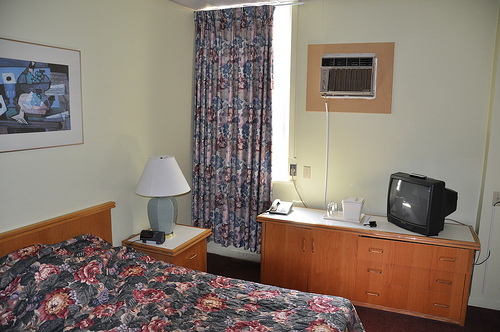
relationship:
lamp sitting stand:
[135, 155, 190, 238] [127, 223, 213, 271]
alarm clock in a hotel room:
[139, 224, 166, 244] [1, 2, 495, 330]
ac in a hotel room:
[319, 53, 378, 102] [5, 5, 491, 324]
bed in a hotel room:
[1, 201, 368, 329] [5, 5, 491, 324]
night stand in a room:
[120, 215, 221, 283] [5, 5, 491, 324]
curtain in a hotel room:
[190, 24, 295, 256] [25, 17, 477, 325]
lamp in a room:
[135, 155, 190, 237] [5, 5, 491, 324]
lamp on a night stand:
[135, 155, 190, 238] [124, 195, 204, 247]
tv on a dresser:
[382, 170, 461, 239] [254, 192, 476, 322]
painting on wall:
[0, 28, 84, 152] [417, 115, 462, 152]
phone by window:
[269, 198, 294, 215] [272, 29, 292, 185]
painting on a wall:
[0, 28, 84, 152] [0, 6, 200, 269]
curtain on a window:
[190, 3, 285, 256] [268, 6, 289, 187]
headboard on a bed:
[0, 200, 121, 280] [14, 190, 346, 330]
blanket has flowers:
[74, 262, 149, 318] [71, 258, 158, 287]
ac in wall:
[319, 53, 378, 102] [150, 1, 499, 309]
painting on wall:
[10, 28, 92, 153] [401, 19, 463, 116]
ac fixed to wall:
[301, 32, 406, 123] [388, 39, 480, 194]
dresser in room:
[258, 205, 480, 326] [5, 5, 491, 324]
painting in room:
[0, 28, 84, 152] [9, 51, 490, 327]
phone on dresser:
[262, 187, 292, 219] [267, 201, 480, 319]